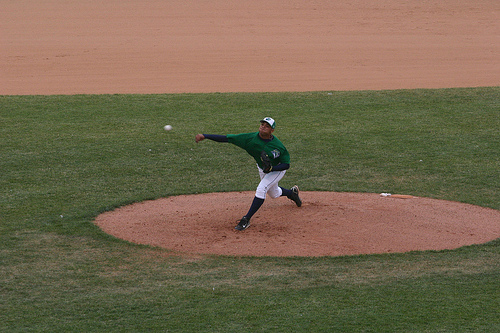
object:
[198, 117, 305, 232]
baseball pitcher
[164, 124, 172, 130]
ball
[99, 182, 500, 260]
pitcher mound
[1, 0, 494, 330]
baseball field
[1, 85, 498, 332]
manicured lawn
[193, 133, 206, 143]
hand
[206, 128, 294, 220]
uniform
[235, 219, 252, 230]
cleat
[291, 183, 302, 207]
cleat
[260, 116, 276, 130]
cap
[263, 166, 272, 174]
glove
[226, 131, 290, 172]
top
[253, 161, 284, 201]
pants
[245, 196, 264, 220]
sock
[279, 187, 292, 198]
sock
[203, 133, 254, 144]
arm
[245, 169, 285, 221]
leg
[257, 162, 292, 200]
leg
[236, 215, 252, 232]
foot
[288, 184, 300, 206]
foot